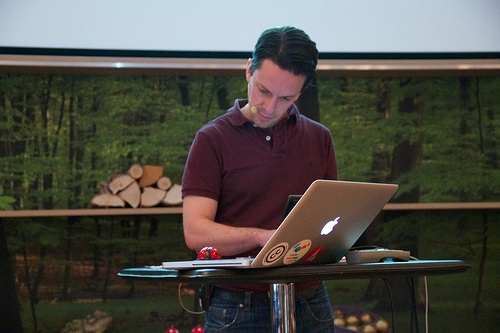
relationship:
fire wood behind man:
[157, 177, 172, 190] [180, 25, 337, 333]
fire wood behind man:
[163, 182, 188, 202] [180, 25, 337, 333]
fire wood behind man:
[138, 163, 165, 183] [180, 25, 337, 333]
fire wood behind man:
[118, 181, 142, 209] [180, 25, 337, 333]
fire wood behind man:
[91, 192, 126, 208] [180, 25, 337, 333]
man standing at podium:
[182, 20, 359, 272] [121, 244, 468, 331]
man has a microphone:
[180, 25, 337, 333] [241, 71, 261, 116]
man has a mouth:
[180, 25, 337, 333] [253, 110, 280, 124]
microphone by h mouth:
[241, 71, 261, 116] [253, 110, 280, 124]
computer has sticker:
[162, 180, 399, 270] [262, 238, 287, 268]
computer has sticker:
[162, 180, 399, 270] [281, 234, 313, 265]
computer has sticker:
[162, 180, 399, 270] [302, 243, 324, 265]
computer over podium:
[162, 180, 399, 270] [115, 258, 471, 279]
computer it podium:
[162, 180, 399, 270] [115, 258, 471, 279]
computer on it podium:
[162, 180, 399, 270] [115, 258, 471, 279]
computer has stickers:
[162, 180, 399, 270] [269, 243, 350, 264]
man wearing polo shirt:
[180, 25, 337, 333] [180, 96, 339, 294]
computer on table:
[162, 180, 399, 270] [116, 258, 472, 331]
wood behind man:
[89, 164, 181, 208] [180, 25, 337, 333]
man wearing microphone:
[180, 25, 337, 333] [248, 95, 258, 121]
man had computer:
[180, 25, 337, 333] [162, 180, 399, 270]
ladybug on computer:
[193, 243, 223, 264] [136, 176, 418, 276]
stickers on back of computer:
[255, 233, 306, 274] [210, 143, 420, 278]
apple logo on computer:
[316, 212, 345, 239] [162, 180, 399, 270]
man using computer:
[180, 25, 337, 333] [162, 180, 399, 270]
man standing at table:
[180, 25, 337, 333] [114, 244, 466, 292]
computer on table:
[162, 180, 399, 270] [286, 257, 386, 287]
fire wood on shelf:
[90, 192, 127, 209] [49, 190, 164, 232]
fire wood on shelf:
[107, 173, 136, 194] [49, 190, 164, 232]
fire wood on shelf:
[117, 179, 143, 209] [49, 190, 164, 232]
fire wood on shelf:
[128, 163, 147, 181] [49, 190, 164, 232]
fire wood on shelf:
[155, 176, 173, 193] [49, 190, 164, 232]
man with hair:
[180, 25, 337, 333] [247, 27, 318, 94]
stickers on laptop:
[264, 239, 320, 264] [215, 168, 392, 285]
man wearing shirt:
[180, 25, 337, 333] [178, 97, 341, 292]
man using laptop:
[180, 25, 337, 333] [173, 192, 354, 282]